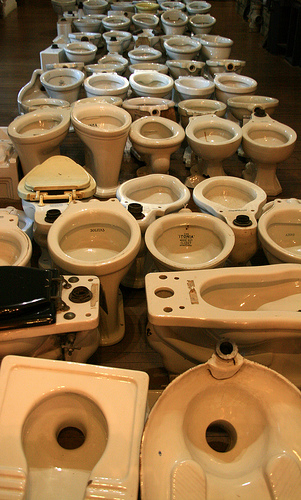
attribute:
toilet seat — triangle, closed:
[23, 149, 92, 193]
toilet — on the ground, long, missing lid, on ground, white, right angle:
[137, 258, 298, 328]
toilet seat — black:
[2, 264, 59, 332]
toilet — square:
[2, 343, 149, 498]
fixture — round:
[52, 196, 135, 275]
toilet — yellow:
[133, 2, 162, 14]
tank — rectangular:
[39, 40, 67, 62]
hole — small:
[178, 299, 185, 313]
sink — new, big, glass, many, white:
[138, 345, 296, 500]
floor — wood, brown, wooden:
[243, 30, 297, 105]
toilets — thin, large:
[48, 13, 243, 75]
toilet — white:
[37, 63, 85, 93]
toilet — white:
[82, 69, 129, 95]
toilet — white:
[129, 65, 170, 94]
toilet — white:
[173, 73, 215, 101]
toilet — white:
[214, 70, 258, 95]